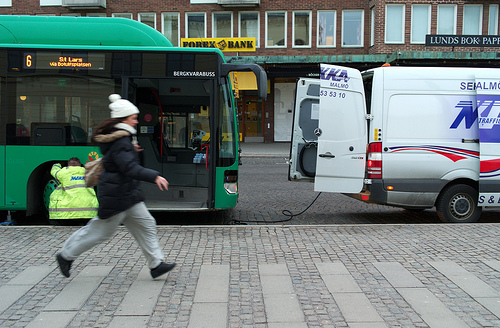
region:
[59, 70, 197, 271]
the woman is running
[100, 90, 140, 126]
woman wearing white hat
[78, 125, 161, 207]
woman wearing black jacket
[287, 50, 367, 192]
van doors are open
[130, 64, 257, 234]
the bus door is open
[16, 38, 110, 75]
orange numbers on bus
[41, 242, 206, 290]
woman's shoes are black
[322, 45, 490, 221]
the van is white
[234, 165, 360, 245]
black cable coming from van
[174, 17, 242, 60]
yellow sign to left of van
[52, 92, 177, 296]
woman walking on sidewalk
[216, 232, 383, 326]
cobblestone sidewalk with concrete strips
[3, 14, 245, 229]
green bus beside curb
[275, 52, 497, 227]
white van in front of green bus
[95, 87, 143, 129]
white winter knit beanie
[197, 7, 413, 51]
row of second story windows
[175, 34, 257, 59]
yellow bank sign over entry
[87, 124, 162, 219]
black winter coat with hood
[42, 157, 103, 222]
yellow safety coat on man at bus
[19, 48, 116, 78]
digital information sign on bus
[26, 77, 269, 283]
woman running down wide sidewalk in city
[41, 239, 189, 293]
woman's feet are not touching ground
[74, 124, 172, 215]
woman wearing black coat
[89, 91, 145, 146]
woman wearing white hat and scarf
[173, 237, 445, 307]
brick and stone pattern in the sidewalk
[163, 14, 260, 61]
yellow sign above door across the street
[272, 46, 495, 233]
back half of white van parked on street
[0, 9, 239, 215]
green bus in need of service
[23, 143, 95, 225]
man looking at bus wheel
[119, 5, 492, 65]
windows above businesses across the street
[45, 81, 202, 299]
A woman is walking.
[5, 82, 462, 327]
The woman walks on a sidewalk.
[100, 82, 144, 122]
The woman wears a white hat.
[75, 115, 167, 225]
The woman wears a parka.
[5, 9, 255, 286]
The woman passes a bus.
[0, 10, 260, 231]
The bus is green.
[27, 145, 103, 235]
A man looks at the bus's tire.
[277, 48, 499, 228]
A van is parked in front of the bus.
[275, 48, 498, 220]
The van is white.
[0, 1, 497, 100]
A building is behind the vehicles.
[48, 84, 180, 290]
woman running on sidewalk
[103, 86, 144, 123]
white hat with pom pom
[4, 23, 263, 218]
green bus on open door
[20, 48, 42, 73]
number side of bus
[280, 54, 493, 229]
white van on side of road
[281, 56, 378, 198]
open doors on back of van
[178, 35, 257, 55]
yellow sign with black letters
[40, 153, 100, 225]
crouched man in yellow coat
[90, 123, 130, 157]
hood on back of coat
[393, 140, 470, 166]
design on side of truck